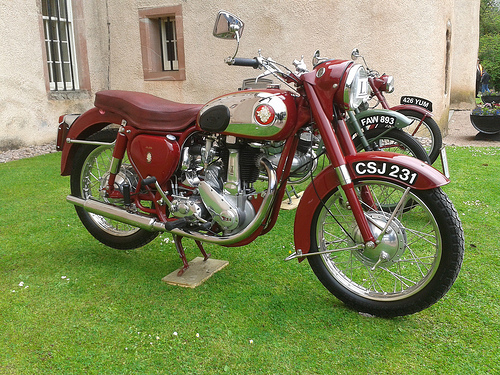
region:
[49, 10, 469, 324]
Three motorbikes sitting on a lawn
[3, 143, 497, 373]
Green lawn with the grass cut short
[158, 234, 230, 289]
Motorcycle kickstand on pad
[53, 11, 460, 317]
Red motorcycle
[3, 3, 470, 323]
Motorcycles parked in front of a white building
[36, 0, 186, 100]
Two windows covered with black iron bars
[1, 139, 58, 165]
Gravel between the lawn and the building wall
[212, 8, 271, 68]
Rearview mirror mounted on a motorcycle handle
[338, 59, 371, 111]
Headlight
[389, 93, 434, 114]
Front fender license plate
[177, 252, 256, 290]
kickstand is on a piece of wood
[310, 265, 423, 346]
motorcycle is in the grass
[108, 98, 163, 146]
motorcycle is red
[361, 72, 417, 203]
three motorcycles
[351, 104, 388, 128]
green motorcycle between the red ones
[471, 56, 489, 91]
person on the side of building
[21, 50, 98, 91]
bars on the window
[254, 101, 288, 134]
red circle on the tank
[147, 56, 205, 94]
bricks around the window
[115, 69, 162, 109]
red seat on the motorcycle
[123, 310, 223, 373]
white flowers in grass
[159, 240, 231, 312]
piece of wood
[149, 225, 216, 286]
kickstand for the bike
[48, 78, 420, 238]
the bike is red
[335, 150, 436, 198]
csj231 written in white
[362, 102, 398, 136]
faw893 written in white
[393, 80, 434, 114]
426yum written in white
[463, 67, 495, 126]
flower pots in background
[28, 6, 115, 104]
bars on the window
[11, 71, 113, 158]
building behind the bike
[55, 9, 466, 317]
A red motorcycle.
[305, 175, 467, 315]
A black motorcycle wheel.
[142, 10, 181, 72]
A window on the side of a building.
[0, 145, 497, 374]
A green grass lawn.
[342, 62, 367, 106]
A round headlight.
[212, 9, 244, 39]
A silver side mirror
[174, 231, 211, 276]
A motorcycle kick stand.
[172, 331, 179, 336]
A small white flower.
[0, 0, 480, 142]
A stucko house behind motorcycle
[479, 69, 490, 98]
A man standing in the distance.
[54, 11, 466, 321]
three motorbikes are parked on the grass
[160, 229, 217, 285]
the kickstand is on a board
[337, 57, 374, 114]
the motor bike has a headlamp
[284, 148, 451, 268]
the front fender is red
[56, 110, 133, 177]
the rear fender is red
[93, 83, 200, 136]
the seat is red leather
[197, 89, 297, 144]
the gas tank is silver and red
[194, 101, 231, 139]
a black thigh protector is on the gas tank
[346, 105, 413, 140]
the motorbike has a gray fender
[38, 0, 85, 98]
black bars are on the window